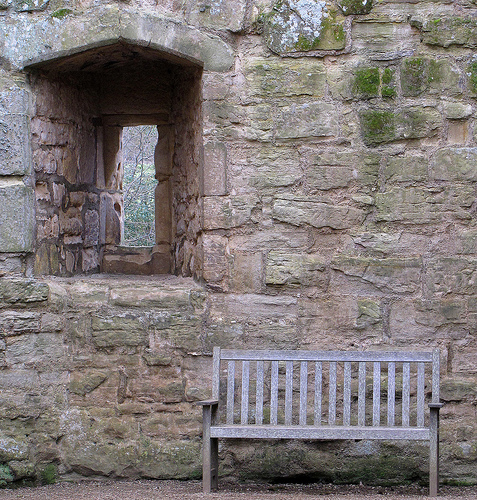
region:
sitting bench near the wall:
[195, 346, 447, 498]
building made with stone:
[229, 50, 475, 313]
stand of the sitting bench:
[194, 432, 219, 498]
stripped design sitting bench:
[225, 359, 419, 428]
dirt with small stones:
[88, 479, 189, 498]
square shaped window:
[9, 60, 213, 297]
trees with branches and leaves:
[128, 133, 149, 251]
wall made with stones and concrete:
[28, 26, 218, 62]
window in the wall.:
[14, 30, 233, 305]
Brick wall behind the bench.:
[4, 0, 474, 497]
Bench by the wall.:
[186, 342, 453, 496]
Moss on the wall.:
[354, 62, 401, 147]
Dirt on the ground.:
[0, 477, 473, 498]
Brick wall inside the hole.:
[32, 77, 115, 269]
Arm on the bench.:
[425, 396, 445, 411]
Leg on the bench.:
[424, 411, 440, 496]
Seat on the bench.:
[208, 421, 438, 442]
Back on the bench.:
[213, 346, 437, 427]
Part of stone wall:
[91, 309, 154, 357]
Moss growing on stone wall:
[351, 62, 383, 105]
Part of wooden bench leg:
[193, 438, 225, 493]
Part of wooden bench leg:
[420, 447, 442, 489]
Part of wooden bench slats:
[216, 349, 266, 397]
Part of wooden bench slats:
[279, 357, 330, 400]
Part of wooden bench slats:
[339, 359, 372, 410]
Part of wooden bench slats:
[404, 365, 440, 399]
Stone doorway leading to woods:
[104, 113, 173, 258]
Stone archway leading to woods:
[6, 12, 237, 81]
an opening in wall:
[118, 119, 162, 256]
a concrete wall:
[1, 2, 473, 499]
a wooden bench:
[196, 341, 444, 493]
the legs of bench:
[199, 443, 438, 498]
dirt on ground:
[0, 481, 474, 495]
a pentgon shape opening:
[13, 3, 233, 308]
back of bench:
[209, 346, 433, 423]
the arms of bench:
[201, 398, 436, 432]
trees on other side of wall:
[123, 127, 154, 249]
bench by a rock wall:
[187, 318, 473, 484]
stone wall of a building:
[18, 308, 165, 451]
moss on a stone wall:
[339, 53, 413, 145]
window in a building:
[105, 106, 169, 257]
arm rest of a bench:
[187, 388, 229, 427]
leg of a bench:
[421, 440, 443, 494]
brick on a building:
[203, 143, 226, 196]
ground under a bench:
[45, 477, 155, 497]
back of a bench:
[230, 359, 418, 423]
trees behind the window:
[127, 134, 148, 232]